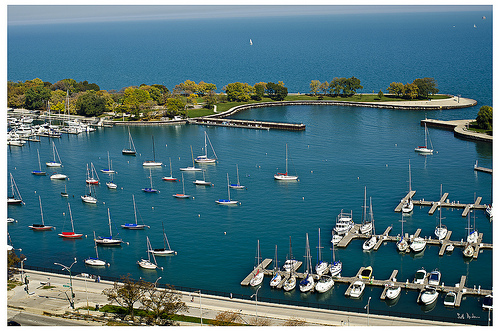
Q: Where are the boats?
A: The water.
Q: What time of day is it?
A: Morning.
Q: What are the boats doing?
A: Floating.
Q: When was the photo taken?
A: Day time.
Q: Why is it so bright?
A: Sunny.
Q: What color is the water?
A: Blue.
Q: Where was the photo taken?
A: At a marina.